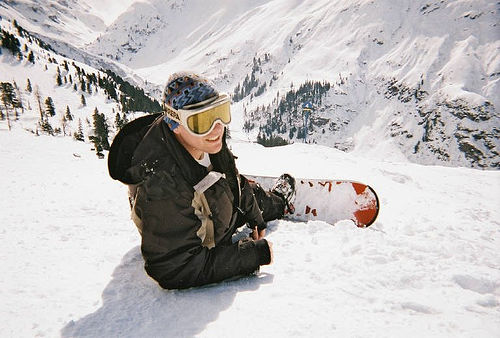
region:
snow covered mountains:
[13, 4, 129, 140]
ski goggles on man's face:
[156, 91, 246, 143]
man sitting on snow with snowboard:
[92, 65, 384, 295]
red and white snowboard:
[288, 163, 388, 234]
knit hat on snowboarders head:
[157, 62, 235, 139]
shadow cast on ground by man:
[86, 261, 258, 336]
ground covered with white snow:
[312, 233, 452, 325]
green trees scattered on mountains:
[27, 58, 98, 149]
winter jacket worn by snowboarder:
[105, 131, 287, 288]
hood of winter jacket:
[99, 101, 169, 196]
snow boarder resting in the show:
[92, 66, 395, 304]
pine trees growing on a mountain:
[256, 71, 335, 148]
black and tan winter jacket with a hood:
[99, 123, 289, 288]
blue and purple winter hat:
[161, 77, 217, 112]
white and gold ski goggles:
[158, 94, 252, 138]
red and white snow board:
[239, 170, 383, 232]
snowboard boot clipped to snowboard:
[264, 175, 300, 225]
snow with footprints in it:
[384, 180, 499, 330]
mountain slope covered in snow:
[263, 5, 493, 142]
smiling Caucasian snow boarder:
[152, 71, 239, 169]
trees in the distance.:
[94, 72, 149, 102]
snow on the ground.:
[26, 191, 83, 226]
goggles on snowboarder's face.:
[192, 115, 227, 124]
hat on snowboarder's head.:
[172, 80, 205, 105]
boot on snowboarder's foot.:
[279, 178, 294, 195]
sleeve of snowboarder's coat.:
[156, 174, 187, 256]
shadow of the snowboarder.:
[110, 293, 155, 320]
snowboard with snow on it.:
[315, 185, 370, 215]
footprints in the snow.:
[424, 225, 476, 279]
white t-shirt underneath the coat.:
[198, 157, 213, 166]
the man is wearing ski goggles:
[127, 70, 273, 155]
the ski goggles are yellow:
[171, 80, 266, 170]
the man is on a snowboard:
[246, 140, 456, 300]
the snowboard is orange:
[260, 150, 446, 245]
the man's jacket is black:
[80, 80, 270, 280]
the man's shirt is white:
[161, 136, 238, 188]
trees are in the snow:
[10, 30, 212, 230]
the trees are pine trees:
[0, 35, 170, 251]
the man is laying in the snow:
[85, 81, 475, 332]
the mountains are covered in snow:
[119, 6, 496, 138]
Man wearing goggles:
[160, 63, 250, 155]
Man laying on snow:
[41, 10, 476, 306]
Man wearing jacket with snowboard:
[80, 40, 385, 300]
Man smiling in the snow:
[80, 20, 457, 320]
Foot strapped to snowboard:
[230, 156, 390, 246]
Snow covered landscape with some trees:
[247, 15, 487, 155]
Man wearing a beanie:
[111, 70, 296, 306]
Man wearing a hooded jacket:
[100, 50, 295, 315]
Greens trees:
[17, 50, 134, 160]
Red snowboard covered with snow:
[263, 164, 398, 249]